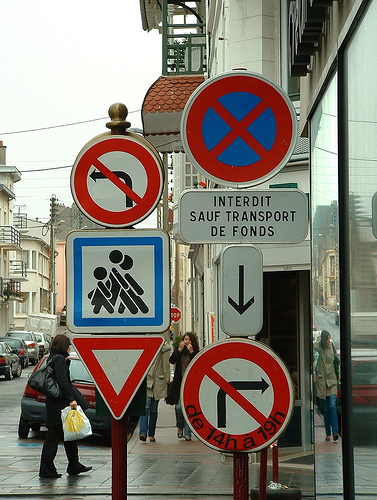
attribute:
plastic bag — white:
[59, 407, 97, 442]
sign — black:
[177, 67, 299, 187]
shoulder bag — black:
[28, 353, 64, 400]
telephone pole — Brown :
[43, 190, 66, 322]